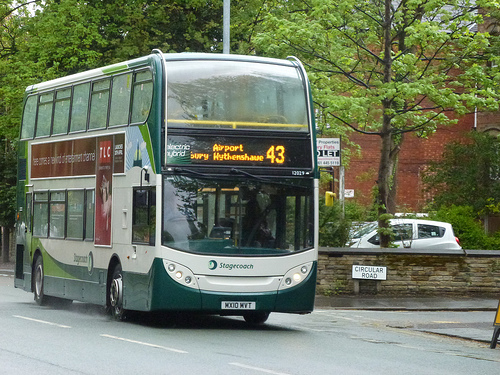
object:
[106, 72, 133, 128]
window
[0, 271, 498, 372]
road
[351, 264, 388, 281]
sign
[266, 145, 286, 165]
43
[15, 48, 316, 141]
top level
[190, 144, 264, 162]
letters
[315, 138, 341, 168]
sign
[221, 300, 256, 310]
license plate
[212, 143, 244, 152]
word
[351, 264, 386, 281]
brown sign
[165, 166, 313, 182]
wiper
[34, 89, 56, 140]
window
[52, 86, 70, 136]
window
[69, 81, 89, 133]
window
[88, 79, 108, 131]
window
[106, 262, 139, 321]
front tire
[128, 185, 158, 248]
window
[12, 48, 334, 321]
bus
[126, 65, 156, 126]
window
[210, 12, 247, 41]
metal pole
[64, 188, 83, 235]
window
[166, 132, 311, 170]
sign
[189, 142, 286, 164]
led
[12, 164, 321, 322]
bottom level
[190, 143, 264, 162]
digital display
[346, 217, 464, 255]
car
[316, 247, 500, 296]
wall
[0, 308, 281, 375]
traffic lines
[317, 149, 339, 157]
letters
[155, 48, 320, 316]
front